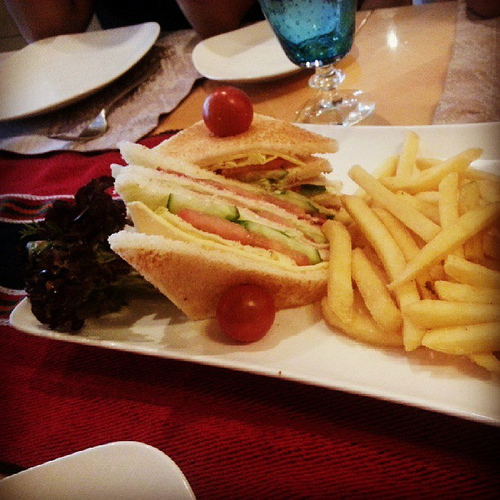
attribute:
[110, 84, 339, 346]
sandwich — tasty, cut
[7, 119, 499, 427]
plate — white, oddly shaped, lovely, rectangular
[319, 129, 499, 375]
french fries — piled, delivered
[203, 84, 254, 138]
cherry tomato — round, small, red, garnish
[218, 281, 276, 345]
cherry tomato — round, small, red, garnish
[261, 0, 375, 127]
glass — blue, dotted, white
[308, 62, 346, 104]
stem — clear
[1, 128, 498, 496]
runner — red, black, dark red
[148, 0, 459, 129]
table — blonde, wooden, shiny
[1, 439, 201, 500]
plate — white, curved, lovely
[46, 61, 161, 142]
fork — metal, silver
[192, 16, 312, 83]
plate — small, empty, white, lovely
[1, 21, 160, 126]
plate — white, lovely, empty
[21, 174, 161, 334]
garnish — purple, green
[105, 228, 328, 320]
bread — toasted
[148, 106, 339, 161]
bread — toasted